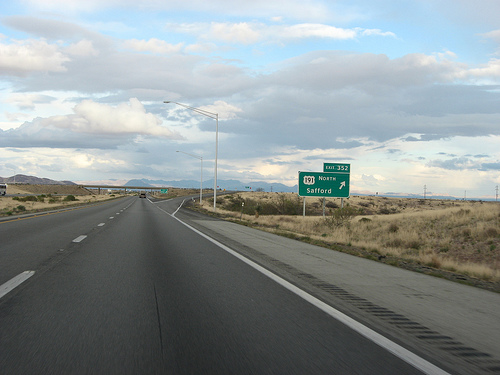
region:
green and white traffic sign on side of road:
[286, 150, 363, 222]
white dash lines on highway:
[1, 200, 128, 305]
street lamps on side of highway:
[159, 95, 229, 210]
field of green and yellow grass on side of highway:
[201, 183, 498, 293]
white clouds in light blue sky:
[43, 92, 186, 154]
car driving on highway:
[133, 190, 151, 207]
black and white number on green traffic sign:
[298, 173, 320, 190]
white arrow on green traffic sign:
[333, 175, 351, 192]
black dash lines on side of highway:
[191, 211, 497, 373]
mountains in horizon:
[0, 168, 82, 193]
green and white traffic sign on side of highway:
[291, 148, 363, 224]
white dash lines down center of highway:
[1, 205, 123, 316]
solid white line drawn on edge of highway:
[184, 223, 404, 372]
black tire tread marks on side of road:
[236, 243, 472, 374]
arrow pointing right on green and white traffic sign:
[332, 177, 354, 191]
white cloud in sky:
[17, 94, 196, 166]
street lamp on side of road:
[144, 94, 236, 219]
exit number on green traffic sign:
[321, 158, 358, 174]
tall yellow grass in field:
[321, 195, 498, 289]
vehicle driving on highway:
[134, 188, 154, 205]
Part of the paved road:
[125, 243, 210, 323]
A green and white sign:
[296, 170, 353, 198]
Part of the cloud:
[88, 108, 125, 128]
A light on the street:
[161, 97, 223, 208]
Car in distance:
[136, 190, 146, 200]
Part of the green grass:
[320, 238, 337, 246]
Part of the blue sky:
[406, 18, 433, 41]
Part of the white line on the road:
[241, 256, 258, 270]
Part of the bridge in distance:
[101, 182, 117, 190]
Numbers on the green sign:
[334, 163, 352, 172]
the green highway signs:
[299, 164, 350, 199]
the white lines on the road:
[2, 194, 452, 373]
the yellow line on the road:
[0, 196, 128, 224]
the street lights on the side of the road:
[161, 98, 220, 205]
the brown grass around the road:
[5, 183, 499, 288]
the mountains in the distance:
[0, 173, 498, 202]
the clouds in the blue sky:
[0, 0, 498, 197]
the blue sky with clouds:
[0, 0, 499, 197]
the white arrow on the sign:
[337, 179, 345, 189]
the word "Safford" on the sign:
[305, 185, 332, 193]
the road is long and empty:
[0, 195, 487, 372]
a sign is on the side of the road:
[295, 169, 349, 197]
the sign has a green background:
[298, 172, 350, 197]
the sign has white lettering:
[300, 170, 347, 195]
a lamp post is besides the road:
[159, 94, 222, 211]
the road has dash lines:
[10, 196, 150, 336]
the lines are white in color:
[4, 191, 146, 318]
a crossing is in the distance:
[73, 183, 175, 197]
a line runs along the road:
[170, 195, 447, 373]